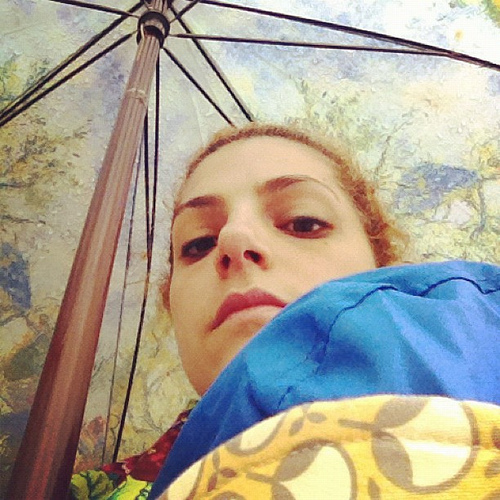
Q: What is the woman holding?
A: Umbrella.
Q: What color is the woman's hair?
A: Red.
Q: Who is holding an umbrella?
A: A female.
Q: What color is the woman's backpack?
A: Blue and yellow.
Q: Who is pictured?
A: A woman.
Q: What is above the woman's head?
A: An umbrella.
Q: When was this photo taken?
A: On a rainy day.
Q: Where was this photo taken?
A: Out doors on a rainy day.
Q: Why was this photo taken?
A: She wanted to take a picture of herself.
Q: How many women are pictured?
A: 1.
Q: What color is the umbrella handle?
A: It is brown.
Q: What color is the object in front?
A: It is blue, yellow, and black.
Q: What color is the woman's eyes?
A: Brown.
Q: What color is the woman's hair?
A: Blonde.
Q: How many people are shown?
A: 1.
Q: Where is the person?
A: Under umbrella.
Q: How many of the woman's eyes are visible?
A: 2.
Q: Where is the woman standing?
A: The middle.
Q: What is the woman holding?
A: An umbrella.